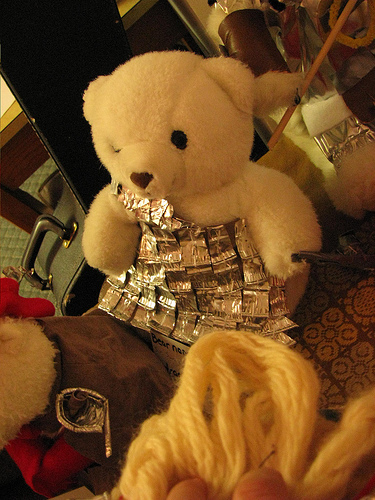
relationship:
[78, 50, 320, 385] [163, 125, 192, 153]
teddy bear has eye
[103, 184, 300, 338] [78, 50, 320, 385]
dress of a teddy bear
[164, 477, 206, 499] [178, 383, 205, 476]
finger on string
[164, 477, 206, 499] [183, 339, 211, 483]
finger on string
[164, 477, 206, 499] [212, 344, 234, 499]
finger on string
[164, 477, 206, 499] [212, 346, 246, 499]
finger on string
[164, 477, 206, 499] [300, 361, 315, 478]
finger on string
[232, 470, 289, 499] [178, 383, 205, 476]
finger on string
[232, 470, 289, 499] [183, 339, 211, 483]
finger on string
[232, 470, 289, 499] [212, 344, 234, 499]
finger on string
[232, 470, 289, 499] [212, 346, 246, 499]
finger on string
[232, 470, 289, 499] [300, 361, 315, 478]
finger on string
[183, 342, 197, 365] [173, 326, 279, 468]
part of ribbon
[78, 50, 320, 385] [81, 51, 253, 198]
teddy bear has head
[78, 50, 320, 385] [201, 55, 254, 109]
teddy bear has an ear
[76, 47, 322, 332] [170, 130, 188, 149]
bear has an eye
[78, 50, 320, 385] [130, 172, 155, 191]
teddy bear has snout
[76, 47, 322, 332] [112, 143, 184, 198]
bear has nose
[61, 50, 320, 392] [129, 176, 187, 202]
teddy bear has smile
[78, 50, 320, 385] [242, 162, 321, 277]
teddy bear has arm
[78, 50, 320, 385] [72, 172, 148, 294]
teddy bear has right arm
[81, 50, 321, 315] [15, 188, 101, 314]
doll next to bag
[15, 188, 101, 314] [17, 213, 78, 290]
bag has a handle